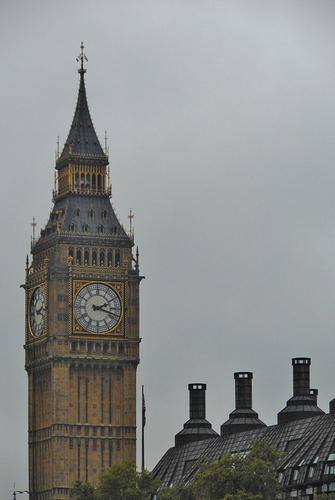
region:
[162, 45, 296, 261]
this is the sky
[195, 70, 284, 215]
the sky is blue in color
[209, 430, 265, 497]
this is a tree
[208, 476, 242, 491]
the leaves are green in color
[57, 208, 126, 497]
this is a building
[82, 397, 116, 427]
this is the wall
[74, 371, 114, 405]
the wall is brown in color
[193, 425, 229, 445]
this is the roof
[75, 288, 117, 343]
this is the clock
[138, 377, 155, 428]
this is a flag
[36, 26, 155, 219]
the top of a clock tower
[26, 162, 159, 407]
the clock tower has a copper color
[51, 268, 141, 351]
the clock reads 2:18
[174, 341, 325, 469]
three chimneys on a tower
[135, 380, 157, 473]
a flag pole in the scene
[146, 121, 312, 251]
a cloudy sky above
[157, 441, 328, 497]
the roof of a bulding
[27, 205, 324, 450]
this clock tower was built many years ago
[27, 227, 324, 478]
this architecture is from the middle ages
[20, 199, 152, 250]
crosses on the tower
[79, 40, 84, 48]
Two round balls on top of the pole on the tower.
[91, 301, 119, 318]
Both hands of a clock facing the camera.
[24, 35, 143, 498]
A tall clock tower with two clocks.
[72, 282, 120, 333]
Round white and black clock facing the camera.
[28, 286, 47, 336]
Clock face on the side of the tower facing left.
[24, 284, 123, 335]
White and black clocks on a tower.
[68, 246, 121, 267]
Seven dark arches above a clock.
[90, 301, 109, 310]
A small black hand on a larger visible clock.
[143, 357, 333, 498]
A three point roof and building that is black and glass to the rigth of a tower.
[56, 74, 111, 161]
A black tiled top steeple.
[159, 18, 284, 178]
this is the sky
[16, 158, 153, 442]
this is the wall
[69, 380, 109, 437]
this is a wall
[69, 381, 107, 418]
the wall is brown in color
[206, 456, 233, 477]
this is a tree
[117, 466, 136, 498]
this is a tree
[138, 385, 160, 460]
this is a flag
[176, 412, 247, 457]
this is a roof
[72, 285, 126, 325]
this is a clock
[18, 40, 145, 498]
Side shot of Big Ben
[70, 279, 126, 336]
Clock face on side of tower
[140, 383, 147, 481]
Tall dark flag pole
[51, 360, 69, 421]
Column of bricks on tower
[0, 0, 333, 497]
Cloudy daytime sky behind tower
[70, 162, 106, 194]
Intricate design on top level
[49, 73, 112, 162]
Portion of dark roofing on tower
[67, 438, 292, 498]
Tops of trees in front of building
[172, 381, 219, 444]
Dark chimney on building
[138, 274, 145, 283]
Stone gargoyle water spout